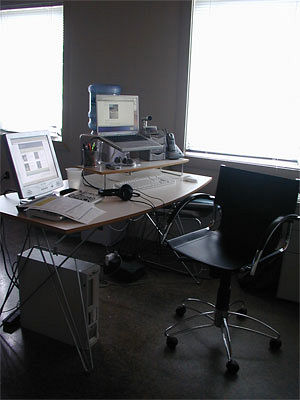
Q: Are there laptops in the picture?
A: Yes, there is a laptop.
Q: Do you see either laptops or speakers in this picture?
A: Yes, there is a laptop.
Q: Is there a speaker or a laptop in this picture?
A: Yes, there is a laptop.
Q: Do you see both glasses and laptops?
A: No, there is a laptop but no glasses.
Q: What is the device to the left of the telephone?
A: The device is a laptop.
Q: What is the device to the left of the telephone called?
A: The device is a laptop.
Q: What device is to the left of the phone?
A: The device is a laptop.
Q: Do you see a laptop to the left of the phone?
A: Yes, there is a laptop to the left of the phone.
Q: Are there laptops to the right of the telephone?
A: No, the laptop is to the left of the telephone.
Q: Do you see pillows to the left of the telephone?
A: No, there is a laptop to the left of the telephone.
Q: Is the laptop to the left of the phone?
A: Yes, the laptop is to the left of the phone.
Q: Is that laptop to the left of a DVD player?
A: No, the laptop is to the left of the phone.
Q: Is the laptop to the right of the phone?
A: No, the laptop is to the left of the phone.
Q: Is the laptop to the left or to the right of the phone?
A: The laptop is to the left of the phone.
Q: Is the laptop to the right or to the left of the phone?
A: The laptop is to the left of the phone.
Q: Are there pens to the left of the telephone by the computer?
A: Yes, there are pens to the left of the telephone.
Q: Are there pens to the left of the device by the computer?
A: Yes, there are pens to the left of the telephone.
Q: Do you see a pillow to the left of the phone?
A: No, there are pens to the left of the phone.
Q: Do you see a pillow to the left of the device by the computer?
A: No, there are pens to the left of the phone.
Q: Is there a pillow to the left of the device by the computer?
A: No, there are pens to the left of the phone.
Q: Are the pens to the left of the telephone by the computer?
A: Yes, the pens are to the left of the phone.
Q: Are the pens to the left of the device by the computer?
A: Yes, the pens are to the left of the phone.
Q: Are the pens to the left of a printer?
A: No, the pens are to the left of the phone.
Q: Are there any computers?
A: Yes, there is a computer.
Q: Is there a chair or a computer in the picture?
A: Yes, there is a computer.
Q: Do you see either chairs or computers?
A: Yes, there is a computer.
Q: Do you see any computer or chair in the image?
A: Yes, there is a computer.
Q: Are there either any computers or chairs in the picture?
A: Yes, there is a computer.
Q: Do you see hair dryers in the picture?
A: No, there are no hair dryers.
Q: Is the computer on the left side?
A: Yes, the computer is on the left of the image.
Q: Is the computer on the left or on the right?
A: The computer is on the left of the image.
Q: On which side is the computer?
A: The computer is on the left of the image.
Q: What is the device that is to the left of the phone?
A: The device is a computer.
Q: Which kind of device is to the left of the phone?
A: The device is a computer.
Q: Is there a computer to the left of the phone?
A: Yes, there is a computer to the left of the phone.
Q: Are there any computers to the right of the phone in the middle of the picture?
A: No, the computer is to the left of the phone.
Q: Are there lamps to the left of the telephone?
A: No, there is a computer to the left of the telephone.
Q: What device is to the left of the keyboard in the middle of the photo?
A: The device is a computer.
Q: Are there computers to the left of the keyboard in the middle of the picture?
A: Yes, there is a computer to the left of the keyboard.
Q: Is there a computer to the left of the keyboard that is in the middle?
A: Yes, there is a computer to the left of the keyboard.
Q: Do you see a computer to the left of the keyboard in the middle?
A: Yes, there is a computer to the left of the keyboard.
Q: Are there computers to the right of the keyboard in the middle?
A: No, the computer is to the left of the keyboard.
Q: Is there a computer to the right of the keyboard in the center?
A: No, the computer is to the left of the keyboard.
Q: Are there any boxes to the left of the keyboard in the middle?
A: No, there is a computer to the left of the keyboard.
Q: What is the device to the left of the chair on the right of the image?
A: The device is a computer.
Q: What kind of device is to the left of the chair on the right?
A: The device is a computer.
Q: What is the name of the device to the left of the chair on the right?
A: The device is a computer.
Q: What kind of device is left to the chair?
A: The device is a computer.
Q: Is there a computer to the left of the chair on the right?
A: Yes, there is a computer to the left of the chair.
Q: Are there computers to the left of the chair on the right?
A: Yes, there is a computer to the left of the chair.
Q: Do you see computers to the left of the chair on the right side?
A: Yes, there is a computer to the left of the chair.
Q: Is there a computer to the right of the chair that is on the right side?
A: No, the computer is to the left of the chair.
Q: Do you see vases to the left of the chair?
A: No, there is a computer to the left of the chair.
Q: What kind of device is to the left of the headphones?
A: The device is a computer.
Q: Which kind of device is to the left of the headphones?
A: The device is a computer.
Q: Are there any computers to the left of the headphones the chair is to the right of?
A: Yes, there is a computer to the left of the headphones.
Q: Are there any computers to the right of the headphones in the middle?
A: No, the computer is to the left of the headphones.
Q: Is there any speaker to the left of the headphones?
A: No, there is a computer to the left of the headphones.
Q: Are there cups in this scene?
A: Yes, there is a cup.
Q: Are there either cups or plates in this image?
A: Yes, there is a cup.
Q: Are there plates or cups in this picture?
A: Yes, there is a cup.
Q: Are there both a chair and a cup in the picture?
A: Yes, there are both a cup and a chair.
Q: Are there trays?
A: No, there are no trays.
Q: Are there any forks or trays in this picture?
A: No, there are no trays or forks.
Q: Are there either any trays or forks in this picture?
A: No, there are no trays or forks.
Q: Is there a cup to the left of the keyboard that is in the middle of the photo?
A: Yes, there is a cup to the left of the keyboard.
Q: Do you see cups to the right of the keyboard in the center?
A: No, the cup is to the left of the keyboard.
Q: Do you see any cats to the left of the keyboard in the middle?
A: No, there is a cup to the left of the keyboard.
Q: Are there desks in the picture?
A: Yes, there is a desk.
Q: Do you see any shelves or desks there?
A: Yes, there is a desk.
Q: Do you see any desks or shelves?
A: Yes, there is a desk.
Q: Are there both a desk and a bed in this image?
A: No, there is a desk but no beds.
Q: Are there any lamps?
A: No, there are no lamps.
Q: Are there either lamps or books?
A: No, there are no lamps or books.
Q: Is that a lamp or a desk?
A: That is a desk.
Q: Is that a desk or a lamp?
A: That is a desk.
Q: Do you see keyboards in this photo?
A: Yes, there is a keyboard.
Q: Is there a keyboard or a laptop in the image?
A: Yes, there is a keyboard.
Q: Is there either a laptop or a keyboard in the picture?
A: Yes, there is a keyboard.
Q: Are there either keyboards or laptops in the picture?
A: Yes, there is a keyboard.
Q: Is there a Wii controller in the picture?
A: No, there are no Wii controllers.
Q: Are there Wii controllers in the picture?
A: No, there are no Wii controllers.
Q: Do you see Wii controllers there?
A: No, there are no Wii controllers.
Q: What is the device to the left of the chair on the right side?
A: The device is a keyboard.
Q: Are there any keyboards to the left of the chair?
A: Yes, there is a keyboard to the left of the chair.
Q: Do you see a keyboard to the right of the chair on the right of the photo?
A: No, the keyboard is to the left of the chair.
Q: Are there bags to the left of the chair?
A: No, there is a keyboard to the left of the chair.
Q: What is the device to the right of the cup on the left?
A: The device is a keyboard.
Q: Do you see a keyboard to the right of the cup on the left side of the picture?
A: Yes, there is a keyboard to the right of the cup.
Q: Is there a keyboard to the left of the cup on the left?
A: No, the keyboard is to the right of the cup.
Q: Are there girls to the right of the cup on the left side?
A: No, there is a keyboard to the right of the cup.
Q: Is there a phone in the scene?
A: Yes, there is a phone.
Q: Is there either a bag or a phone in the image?
A: Yes, there is a phone.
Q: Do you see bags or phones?
A: Yes, there is a phone.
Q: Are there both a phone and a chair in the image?
A: Yes, there are both a phone and a chair.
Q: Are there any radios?
A: No, there are no radios.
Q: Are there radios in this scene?
A: No, there are no radios.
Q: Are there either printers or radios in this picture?
A: No, there are no radios or printers.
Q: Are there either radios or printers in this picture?
A: No, there are no radios or printers.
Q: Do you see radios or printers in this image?
A: No, there are no radios or printers.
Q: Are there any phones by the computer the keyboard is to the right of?
A: Yes, there is a phone by the computer.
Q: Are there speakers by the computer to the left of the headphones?
A: No, there is a phone by the computer.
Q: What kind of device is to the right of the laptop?
A: The device is a phone.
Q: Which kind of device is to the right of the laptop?
A: The device is a phone.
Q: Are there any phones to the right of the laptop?
A: Yes, there is a phone to the right of the laptop.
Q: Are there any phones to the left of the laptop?
A: No, the phone is to the right of the laptop.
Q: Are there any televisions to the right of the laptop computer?
A: No, there is a phone to the right of the laptop computer.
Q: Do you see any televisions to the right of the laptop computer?
A: No, there is a phone to the right of the laptop computer.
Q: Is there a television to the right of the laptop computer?
A: No, there is a phone to the right of the laptop computer.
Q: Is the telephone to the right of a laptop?
A: Yes, the telephone is to the right of a laptop.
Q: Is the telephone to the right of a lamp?
A: No, the telephone is to the right of a laptop.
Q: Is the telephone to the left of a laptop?
A: No, the telephone is to the right of a laptop.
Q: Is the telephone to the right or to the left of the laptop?
A: The telephone is to the right of the laptop.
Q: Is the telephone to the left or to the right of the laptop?
A: The telephone is to the right of the laptop.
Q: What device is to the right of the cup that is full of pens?
A: The device is a phone.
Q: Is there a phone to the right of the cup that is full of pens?
A: Yes, there is a phone to the right of the cup.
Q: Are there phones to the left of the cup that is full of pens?
A: No, the phone is to the right of the cup.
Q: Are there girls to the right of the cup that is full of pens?
A: No, there is a phone to the right of the cup.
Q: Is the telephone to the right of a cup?
A: Yes, the telephone is to the right of a cup.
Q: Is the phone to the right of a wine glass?
A: No, the phone is to the right of a cup.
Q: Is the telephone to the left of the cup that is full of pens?
A: No, the telephone is to the right of the cup.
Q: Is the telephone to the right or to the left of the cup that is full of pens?
A: The telephone is to the right of the cup.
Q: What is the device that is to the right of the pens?
A: The device is a phone.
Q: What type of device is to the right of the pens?
A: The device is a phone.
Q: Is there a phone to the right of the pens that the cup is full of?
A: Yes, there is a phone to the right of the pens.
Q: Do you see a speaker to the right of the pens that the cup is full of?
A: No, there is a phone to the right of the pens.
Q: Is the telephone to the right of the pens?
A: Yes, the telephone is to the right of the pens.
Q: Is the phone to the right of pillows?
A: No, the phone is to the right of the pens.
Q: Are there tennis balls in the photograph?
A: No, there are no tennis balls.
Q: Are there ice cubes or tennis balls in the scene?
A: No, there are no tennis balls or ice cubes.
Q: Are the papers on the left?
A: Yes, the papers are on the left of the image.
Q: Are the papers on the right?
A: No, the papers are on the left of the image.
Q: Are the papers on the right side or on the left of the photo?
A: The papers are on the left of the image.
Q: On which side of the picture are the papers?
A: The papers are on the left of the image.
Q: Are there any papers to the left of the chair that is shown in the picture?
A: Yes, there are papers to the left of the chair.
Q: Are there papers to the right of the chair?
A: No, the papers are to the left of the chair.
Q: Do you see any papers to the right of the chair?
A: No, the papers are to the left of the chair.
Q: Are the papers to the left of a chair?
A: Yes, the papers are to the left of a chair.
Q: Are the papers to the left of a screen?
A: No, the papers are to the left of a chair.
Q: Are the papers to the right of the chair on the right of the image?
A: No, the papers are to the left of the chair.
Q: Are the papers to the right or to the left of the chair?
A: The papers are to the left of the chair.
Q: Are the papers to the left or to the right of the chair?
A: The papers are to the left of the chair.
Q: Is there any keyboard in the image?
A: Yes, there is a keyboard.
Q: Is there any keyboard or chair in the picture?
A: Yes, there is a keyboard.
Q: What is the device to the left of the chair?
A: The device is a keyboard.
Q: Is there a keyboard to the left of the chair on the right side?
A: Yes, there is a keyboard to the left of the chair.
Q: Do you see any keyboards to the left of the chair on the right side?
A: Yes, there is a keyboard to the left of the chair.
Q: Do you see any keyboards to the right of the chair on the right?
A: No, the keyboard is to the left of the chair.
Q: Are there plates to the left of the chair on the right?
A: No, there is a keyboard to the left of the chair.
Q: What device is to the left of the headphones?
A: The device is a keyboard.